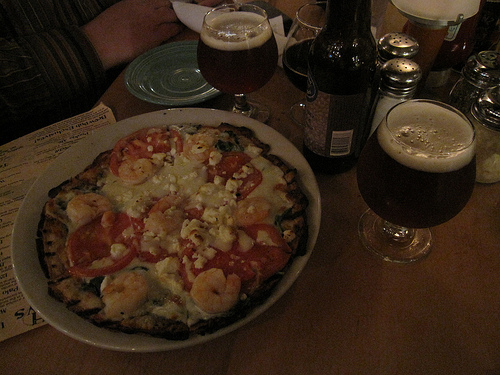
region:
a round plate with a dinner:
[15, 97, 320, 347]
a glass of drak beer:
[352, 103, 478, 268]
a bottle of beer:
[306, 29, 374, 181]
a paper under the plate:
[9, 106, 111, 351]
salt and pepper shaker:
[361, 38, 421, 158]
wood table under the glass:
[356, 92, 496, 291]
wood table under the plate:
[52, 136, 355, 371]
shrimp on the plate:
[106, 256, 156, 325]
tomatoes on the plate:
[90, 203, 152, 282]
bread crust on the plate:
[46, 200, 114, 331]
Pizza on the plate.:
[31, 120, 330, 340]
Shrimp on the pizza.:
[187, 267, 244, 313]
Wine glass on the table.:
[356, 98, 477, 262]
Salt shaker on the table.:
[368, 57, 418, 137]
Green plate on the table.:
[123, 38, 218, 105]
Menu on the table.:
[5, 100, 122, 340]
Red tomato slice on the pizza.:
[66, 207, 141, 277]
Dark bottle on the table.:
[303, 2, 377, 176]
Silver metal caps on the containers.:
[377, 33, 417, 100]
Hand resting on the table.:
[80, 0, 186, 68]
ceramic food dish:
[126, 37, 231, 106]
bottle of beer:
[301, 3, 378, 176]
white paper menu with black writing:
[0, 102, 117, 340]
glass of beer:
[355, 98, 480, 265]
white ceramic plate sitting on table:
[8, 100, 323, 350]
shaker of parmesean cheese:
[470, 82, 496, 178]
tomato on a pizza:
[65, 208, 140, 275]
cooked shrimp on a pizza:
[190, 267, 241, 313]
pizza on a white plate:
[12, 105, 322, 351]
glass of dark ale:
[354, 100, 477, 275]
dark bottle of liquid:
[301, 0, 377, 174]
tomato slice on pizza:
[63, 210, 143, 276]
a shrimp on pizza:
[190, 268, 242, 313]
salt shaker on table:
[371, 57, 422, 143]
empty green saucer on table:
[123, 40, 228, 106]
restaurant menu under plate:
[0, 100, 117, 341]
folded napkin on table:
[171, 0, 301, 69]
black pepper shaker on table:
[448, 48, 496, 117]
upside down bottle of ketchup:
[426, 12, 477, 97]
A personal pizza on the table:
[14, 108, 320, 356]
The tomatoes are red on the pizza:
[63, 207, 292, 296]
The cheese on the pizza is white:
[148, 164, 225, 218]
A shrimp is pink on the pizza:
[182, 260, 245, 317]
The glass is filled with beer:
[353, 93, 480, 268]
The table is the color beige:
[319, 289, 487, 373]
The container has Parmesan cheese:
[466, 83, 498, 189]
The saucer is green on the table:
[121, 40, 238, 108]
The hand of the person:
[73, 2, 200, 74]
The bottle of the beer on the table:
[299, 3, 384, 180]